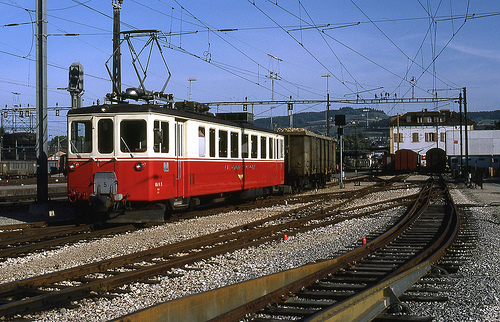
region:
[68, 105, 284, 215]
white and red trolley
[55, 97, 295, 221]
white and red train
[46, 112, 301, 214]
trolley on the tracks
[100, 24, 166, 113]
black top bars to trolley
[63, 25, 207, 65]
wires running above trolley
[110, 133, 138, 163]
window wipers on trolley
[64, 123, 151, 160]
windows on front of trolley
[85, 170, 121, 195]
grey front to trolley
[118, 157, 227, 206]
red bottom of trolley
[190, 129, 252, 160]
windows on side of trolley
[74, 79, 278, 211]
a big red and white train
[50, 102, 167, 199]
the front of a train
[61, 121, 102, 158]
the front window of a train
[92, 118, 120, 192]
the door of a train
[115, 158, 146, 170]
the headlight of a train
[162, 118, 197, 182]
the side door of a train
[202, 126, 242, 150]
the side window of a train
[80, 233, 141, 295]
the brown railroad tracks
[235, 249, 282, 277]
the gravel in the middle of some tracks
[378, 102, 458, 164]
a white house in the background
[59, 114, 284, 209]
train is red and white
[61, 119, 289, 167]
the windows are black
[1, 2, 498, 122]
metal structures above the train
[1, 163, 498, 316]
rocks between the tracks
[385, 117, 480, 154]
white building in background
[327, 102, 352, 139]
the sign is black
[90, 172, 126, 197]
silver part on train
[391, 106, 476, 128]
roof of building is brown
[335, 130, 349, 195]
sign post is silver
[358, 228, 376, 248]
orange object on the track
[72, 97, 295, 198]
An electric train engine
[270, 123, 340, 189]
a cargo carrying train car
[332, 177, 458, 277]
railroad tracks crisscrossing gravel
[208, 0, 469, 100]
electric train power lines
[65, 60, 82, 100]
train traffic lights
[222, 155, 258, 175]
writing on the side of a train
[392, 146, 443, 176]
train cars in the shade of a building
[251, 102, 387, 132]
hills in the distance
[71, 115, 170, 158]
windows in a train car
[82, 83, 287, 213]
train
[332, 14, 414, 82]
white clouds in blue sky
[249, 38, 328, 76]
white clouds in blue sky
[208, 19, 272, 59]
white clouds in blue sky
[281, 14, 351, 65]
white clouds in blue sky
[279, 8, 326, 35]
white clouds in blue sky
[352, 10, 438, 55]
white clouds in blue sky